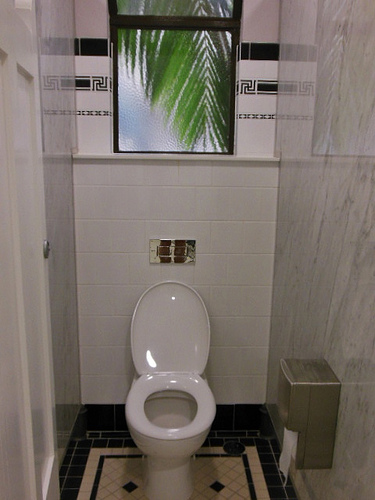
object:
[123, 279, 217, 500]
toilet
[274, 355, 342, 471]
toilet paper holder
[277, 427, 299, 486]
toilet paper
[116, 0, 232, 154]
palm tree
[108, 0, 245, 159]
through window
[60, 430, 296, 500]
floor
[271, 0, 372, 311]
wall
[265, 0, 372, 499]
wall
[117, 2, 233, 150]
window glass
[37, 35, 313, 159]
wall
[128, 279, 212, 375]
toilet seat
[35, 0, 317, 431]
wall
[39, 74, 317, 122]
pattern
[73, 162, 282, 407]
tile wall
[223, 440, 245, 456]
drain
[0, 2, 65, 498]
stall door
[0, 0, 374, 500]
bathroom stall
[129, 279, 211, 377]
lid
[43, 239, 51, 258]
lock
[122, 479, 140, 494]
tile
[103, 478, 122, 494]
floor tile